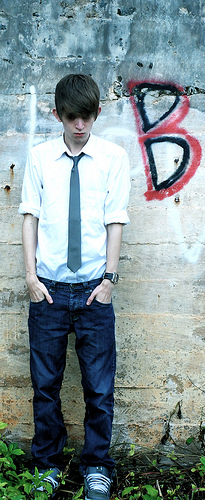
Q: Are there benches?
A: No, there are no benches.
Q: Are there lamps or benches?
A: No, there are no benches or lamps.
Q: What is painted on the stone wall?
A: The graffiti is painted on the wall.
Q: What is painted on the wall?
A: The graffiti is painted on the wall.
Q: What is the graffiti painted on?
A: The graffiti is painted on the wall.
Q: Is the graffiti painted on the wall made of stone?
A: Yes, the graffiti is painted on the wall.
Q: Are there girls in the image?
A: No, there are no girls.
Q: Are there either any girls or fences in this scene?
A: No, there are no girls or fences.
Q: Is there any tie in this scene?
A: Yes, there is a tie.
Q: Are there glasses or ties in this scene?
A: Yes, there is a tie.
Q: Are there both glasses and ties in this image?
A: No, there is a tie but no glasses.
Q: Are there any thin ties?
A: Yes, there is a thin tie.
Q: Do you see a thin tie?
A: Yes, there is a thin tie.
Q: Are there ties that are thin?
A: Yes, there is a tie that is thin.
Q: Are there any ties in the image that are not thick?
A: Yes, there is a thin tie.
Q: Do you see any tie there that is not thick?
A: Yes, there is a thin tie.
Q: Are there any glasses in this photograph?
A: No, there are no glasses.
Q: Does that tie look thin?
A: Yes, the tie is thin.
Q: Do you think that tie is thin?
A: Yes, the tie is thin.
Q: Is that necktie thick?
A: No, the necktie is thin.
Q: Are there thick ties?
A: No, there is a tie but it is thin.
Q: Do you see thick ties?
A: No, there is a tie but it is thin.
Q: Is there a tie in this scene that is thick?
A: No, there is a tie but it is thin.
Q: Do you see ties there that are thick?
A: No, there is a tie but it is thin.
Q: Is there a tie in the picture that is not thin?
A: No, there is a tie but it is thin.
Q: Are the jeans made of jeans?
A: Yes, the jeans are made of jeans.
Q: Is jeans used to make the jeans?
A: Yes, the jeans are made of jeans.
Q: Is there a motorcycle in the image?
A: No, there are no motorcycles.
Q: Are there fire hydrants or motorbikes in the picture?
A: No, there are no motorbikes or fire hydrants.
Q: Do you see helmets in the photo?
A: No, there are no helmets.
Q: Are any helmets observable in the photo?
A: No, there are no helmets.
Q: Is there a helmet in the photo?
A: No, there are no helmets.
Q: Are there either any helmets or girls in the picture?
A: No, there are no helmets or girls.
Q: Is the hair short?
A: Yes, the hair is short.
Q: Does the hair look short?
A: Yes, the hair is short.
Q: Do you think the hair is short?
A: Yes, the hair is short.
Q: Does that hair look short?
A: Yes, the hair is short.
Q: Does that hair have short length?
A: Yes, the hair is short.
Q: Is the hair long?
A: No, the hair is short.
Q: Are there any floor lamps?
A: No, there are no floor lamps.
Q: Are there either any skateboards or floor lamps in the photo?
A: No, there are no floor lamps or skateboards.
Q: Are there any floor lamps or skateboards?
A: No, there are no floor lamps or skateboards.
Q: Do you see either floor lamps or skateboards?
A: No, there are no floor lamps or skateboards.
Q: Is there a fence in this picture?
A: No, there are no fences.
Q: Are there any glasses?
A: No, there are no glasses.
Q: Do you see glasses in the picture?
A: No, there are no glasses.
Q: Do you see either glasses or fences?
A: No, there are no glasses or fences.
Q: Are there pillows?
A: No, there are no pillows.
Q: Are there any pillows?
A: No, there are no pillows.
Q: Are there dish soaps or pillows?
A: No, there are no pillows or dish soaps.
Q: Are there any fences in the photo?
A: No, there are no fences.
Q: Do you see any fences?
A: No, there are no fences.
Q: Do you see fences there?
A: No, there are no fences.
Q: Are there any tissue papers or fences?
A: No, there are no fences or tissue papers.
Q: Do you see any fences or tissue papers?
A: No, there are no fences or tissue papers.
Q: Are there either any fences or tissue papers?
A: No, there are no fences or tissue papers.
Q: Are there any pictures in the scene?
A: No, there are no pictures.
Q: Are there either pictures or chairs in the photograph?
A: No, there are no pictures or chairs.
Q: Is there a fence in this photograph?
A: No, there are no fences.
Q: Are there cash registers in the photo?
A: No, there are no cash registers.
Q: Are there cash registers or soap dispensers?
A: No, there are no cash registers or soap dispensers.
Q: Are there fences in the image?
A: No, there are no fences.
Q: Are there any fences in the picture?
A: No, there are no fences.